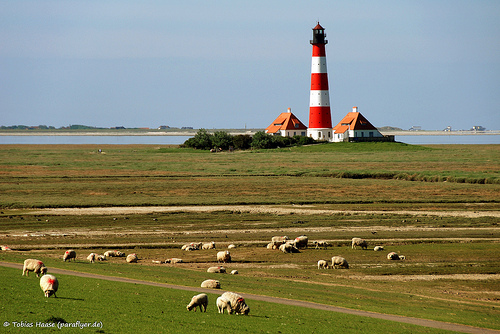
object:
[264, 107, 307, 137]
house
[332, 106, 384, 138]
house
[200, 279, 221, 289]
sheep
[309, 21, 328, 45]
balcony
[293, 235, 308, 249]
sheep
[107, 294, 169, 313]
grass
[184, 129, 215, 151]
trees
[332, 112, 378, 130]
house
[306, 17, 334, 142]
lighthouse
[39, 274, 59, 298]
sheep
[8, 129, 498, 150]
water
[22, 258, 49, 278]
white sheep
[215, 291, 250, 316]
sheep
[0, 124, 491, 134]
sandbar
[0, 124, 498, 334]
field